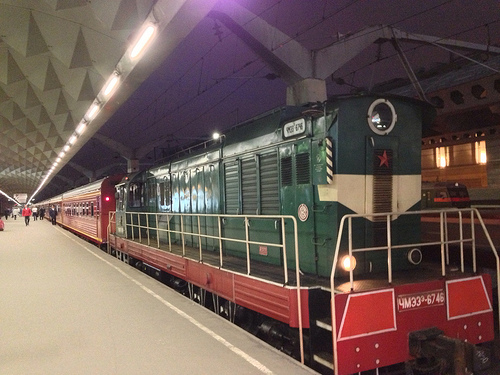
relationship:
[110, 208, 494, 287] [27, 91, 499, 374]
railing on train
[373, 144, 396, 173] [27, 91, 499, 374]
star on train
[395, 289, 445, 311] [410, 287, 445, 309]
tag with numbers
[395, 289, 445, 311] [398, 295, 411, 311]
tag with letters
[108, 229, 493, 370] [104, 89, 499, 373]
bottom of train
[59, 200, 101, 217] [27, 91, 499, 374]
windows on train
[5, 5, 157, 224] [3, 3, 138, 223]
ceiling has shapes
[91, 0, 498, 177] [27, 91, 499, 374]
wires above train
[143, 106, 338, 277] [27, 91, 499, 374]
side of train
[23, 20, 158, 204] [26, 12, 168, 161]
lights along overhang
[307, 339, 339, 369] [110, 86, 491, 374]
step up to engine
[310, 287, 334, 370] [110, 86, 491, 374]
step up to engine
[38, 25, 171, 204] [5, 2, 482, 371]
lights inside building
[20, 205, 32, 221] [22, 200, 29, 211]
person wearing shirt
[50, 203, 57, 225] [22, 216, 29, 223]
person wearing pants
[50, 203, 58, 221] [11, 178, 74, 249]
person wearing dark coat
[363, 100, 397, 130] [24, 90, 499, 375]
round window on train car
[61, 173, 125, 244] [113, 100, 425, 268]
train car behind car